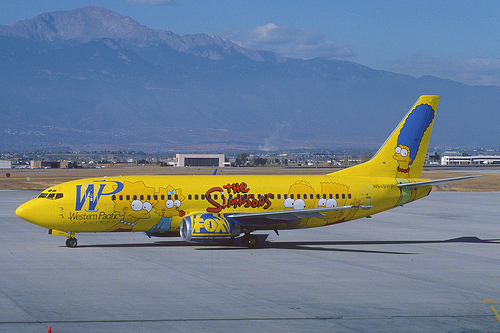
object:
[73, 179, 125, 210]
lettering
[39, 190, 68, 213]
cockpit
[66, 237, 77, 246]
wheel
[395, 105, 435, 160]
paint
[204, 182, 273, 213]
lettering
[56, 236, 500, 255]
shadow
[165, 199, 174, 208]
eyes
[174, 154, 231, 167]
building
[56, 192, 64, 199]
windows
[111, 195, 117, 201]
window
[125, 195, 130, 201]
window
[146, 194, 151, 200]
window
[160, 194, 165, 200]
window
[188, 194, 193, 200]
window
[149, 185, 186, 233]
maggie simpson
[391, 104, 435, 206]
marge simpson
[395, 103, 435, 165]
hair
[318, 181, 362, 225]
bart simpson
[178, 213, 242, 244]
engine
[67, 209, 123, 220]
western pacific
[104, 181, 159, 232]
lisa simpson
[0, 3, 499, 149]
mountain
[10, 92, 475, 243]
side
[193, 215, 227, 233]
fox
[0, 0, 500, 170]
background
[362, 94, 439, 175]
tail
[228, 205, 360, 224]
wing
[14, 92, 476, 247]
airplane